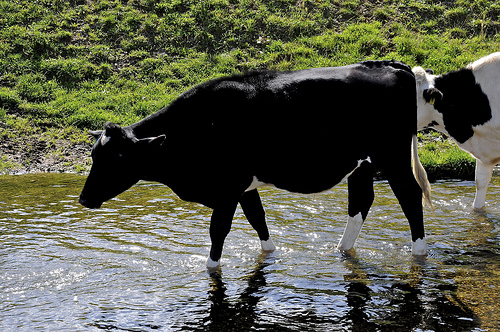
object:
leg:
[204, 202, 235, 269]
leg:
[388, 160, 428, 256]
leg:
[335, 169, 376, 251]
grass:
[0, 0, 500, 165]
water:
[0, 172, 500, 332]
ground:
[0, 0, 500, 332]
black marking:
[422, 66, 494, 146]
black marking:
[422, 120, 439, 129]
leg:
[239, 184, 276, 251]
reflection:
[0, 204, 500, 332]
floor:
[0, 0, 500, 331]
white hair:
[411, 133, 435, 216]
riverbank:
[1, 0, 500, 178]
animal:
[77, 57, 439, 270]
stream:
[0, 165, 500, 332]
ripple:
[0, 171, 500, 332]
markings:
[74, 58, 429, 263]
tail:
[390, 59, 436, 217]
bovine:
[411, 49, 500, 212]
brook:
[0, 167, 500, 332]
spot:
[433, 67, 492, 144]